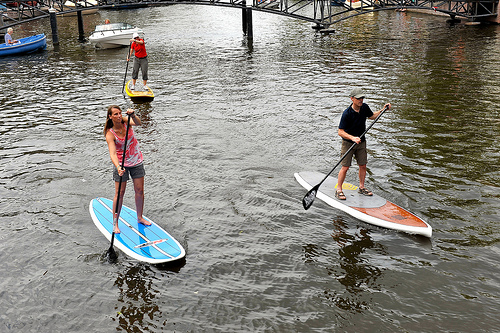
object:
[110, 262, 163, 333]
reflection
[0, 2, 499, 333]
water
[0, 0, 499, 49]
bridge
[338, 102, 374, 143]
t-shirt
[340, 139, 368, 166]
shorts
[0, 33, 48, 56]
blue boat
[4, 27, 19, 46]
man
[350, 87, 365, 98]
cap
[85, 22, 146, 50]
boat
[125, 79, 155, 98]
yellow board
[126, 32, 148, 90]
people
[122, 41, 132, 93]
oars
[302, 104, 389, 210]
oars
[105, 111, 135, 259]
oars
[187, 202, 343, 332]
surface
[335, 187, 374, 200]
sandals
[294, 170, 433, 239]
paddle board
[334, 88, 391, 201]
body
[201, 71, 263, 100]
sky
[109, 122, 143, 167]
tank top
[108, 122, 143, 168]
shirt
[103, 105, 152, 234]
people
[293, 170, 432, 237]
surfboard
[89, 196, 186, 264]
surfboard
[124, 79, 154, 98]
surfboard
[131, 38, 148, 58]
shirt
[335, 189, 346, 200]
foot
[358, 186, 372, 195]
foot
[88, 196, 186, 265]
boat